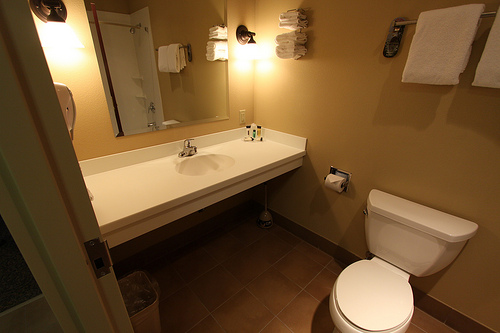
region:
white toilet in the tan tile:
[321, 171, 490, 327]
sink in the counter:
[164, 129, 249, 198]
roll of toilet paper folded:
[311, 165, 357, 200]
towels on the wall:
[268, 10, 303, 83]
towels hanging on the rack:
[394, 10, 497, 85]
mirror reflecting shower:
[102, 17, 247, 165]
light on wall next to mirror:
[234, 27, 269, 67]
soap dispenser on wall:
[51, 75, 95, 179]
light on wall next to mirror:
[43, 2, 88, 89]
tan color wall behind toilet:
[306, 60, 464, 265]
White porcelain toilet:
[327, 191, 467, 326]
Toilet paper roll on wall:
[322, 161, 350, 202]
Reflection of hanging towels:
[150, 32, 191, 78]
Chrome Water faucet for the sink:
[175, 133, 200, 158]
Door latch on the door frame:
[75, 230, 121, 282]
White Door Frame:
[0, 10, 130, 330]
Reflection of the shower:
[88, 6, 164, 136]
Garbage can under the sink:
[115, 270, 163, 330]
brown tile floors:
[165, 240, 297, 331]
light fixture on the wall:
[236, 26, 272, 82]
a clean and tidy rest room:
[82, 10, 467, 329]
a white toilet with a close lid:
[330, 185, 478, 330]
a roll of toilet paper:
[322, 172, 345, 193]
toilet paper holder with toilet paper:
[322, 161, 348, 187]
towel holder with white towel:
[377, 1, 492, 112]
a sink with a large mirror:
[97, 0, 307, 195]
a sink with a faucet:
[157, 125, 237, 186]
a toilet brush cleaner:
[255, 182, 277, 245]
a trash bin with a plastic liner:
[115, 270, 161, 321]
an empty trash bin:
[117, 272, 167, 332]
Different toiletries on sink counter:
[243, 117, 265, 139]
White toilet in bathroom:
[325, 181, 482, 329]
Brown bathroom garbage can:
[118, 267, 168, 330]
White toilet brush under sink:
[259, 187, 276, 234]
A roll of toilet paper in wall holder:
[321, 163, 355, 195]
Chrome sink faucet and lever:
[177, 131, 199, 157]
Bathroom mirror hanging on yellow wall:
[81, 10, 238, 140]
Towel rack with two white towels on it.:
[380, 0, 498, 95]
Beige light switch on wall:
[237, 105, 249, 125]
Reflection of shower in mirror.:
[87, 8, 166, 138]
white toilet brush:
[258, 184, 278, 232]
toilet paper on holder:
[315, 167, 352, 196]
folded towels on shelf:
[262, 12, 319, 67]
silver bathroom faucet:
[168, 133, 201, 159]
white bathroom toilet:
[326, 249, 413, 331]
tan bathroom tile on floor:
[242, 267, 304, 317]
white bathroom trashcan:
[116, 261, 187, 332]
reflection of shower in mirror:
[88, 6, 161, 143]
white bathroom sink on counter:
[167, 148, 245, 190]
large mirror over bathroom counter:
[81, 0, 225, 147]